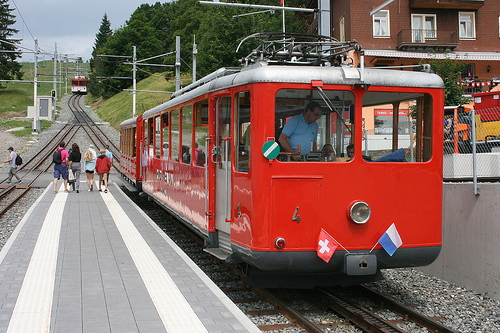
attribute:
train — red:
[116, 62, 444, 291]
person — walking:
[95, 150, 110, 193]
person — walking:
[83, 151, 98, 192]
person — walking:
[68, 144, 83, 193]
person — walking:
[54, 141, 70, 193]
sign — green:
[260, 138, 281, 162]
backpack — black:
[15, 152, 22, 166]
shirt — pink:
[53, 146, 69, 162]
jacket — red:
[96, 155, 112, 173]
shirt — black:
[68, 149, 81, 162]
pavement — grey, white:
[1, 179, 264, 333]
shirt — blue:
[284, 113, 318, 152]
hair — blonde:
[83, 146, 96, 161]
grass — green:
[92, 64, 191, 131]